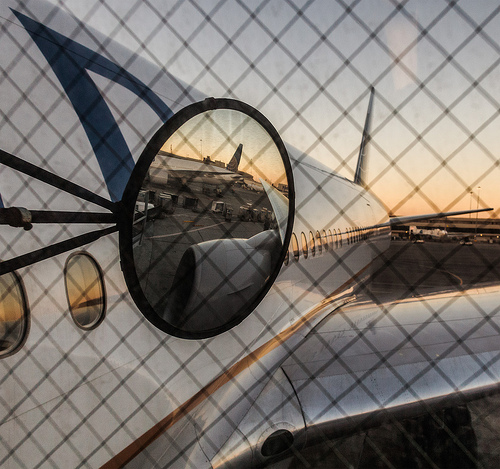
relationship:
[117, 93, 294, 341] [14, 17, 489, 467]
side view mirror on plane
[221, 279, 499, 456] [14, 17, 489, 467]
wing on plane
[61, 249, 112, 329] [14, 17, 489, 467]
window on plane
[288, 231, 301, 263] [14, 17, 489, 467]
window on plane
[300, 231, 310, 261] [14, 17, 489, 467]
window on plane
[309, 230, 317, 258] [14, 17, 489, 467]
window on plane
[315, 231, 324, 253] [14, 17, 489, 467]
window on plane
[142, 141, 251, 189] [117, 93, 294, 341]
plane reflected on side view mirror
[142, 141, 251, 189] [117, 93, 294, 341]
plane reflected in side view mirror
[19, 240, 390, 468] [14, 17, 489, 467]
stripe on plane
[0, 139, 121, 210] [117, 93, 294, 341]
pole supporting side view mirror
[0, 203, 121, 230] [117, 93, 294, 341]
pole supporting side view mirror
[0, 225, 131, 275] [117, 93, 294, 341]
pole supporting side view mirror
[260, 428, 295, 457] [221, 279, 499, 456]
circle on wing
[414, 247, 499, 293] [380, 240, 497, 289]
lines on ground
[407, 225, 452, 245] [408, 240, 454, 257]
airplane on ground